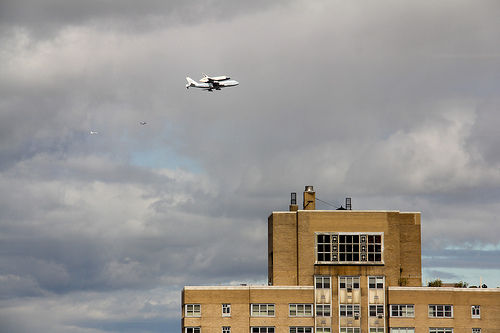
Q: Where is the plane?
A: In the ir.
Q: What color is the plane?
A: White.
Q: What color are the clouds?
A: Gray.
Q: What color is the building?
A: Brown.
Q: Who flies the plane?
A: A pilot.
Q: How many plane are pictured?
A: One.